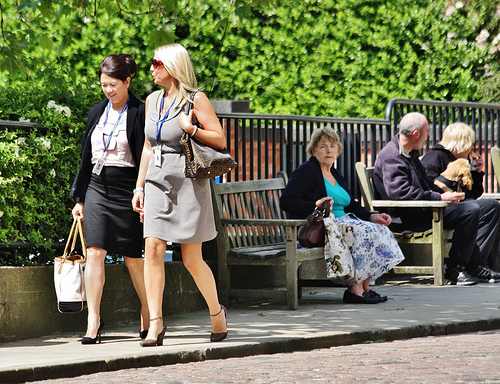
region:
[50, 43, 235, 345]
two women walking on the sidewalk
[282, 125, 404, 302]
a woman sitting on the bench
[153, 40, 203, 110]
the blonde hair of the woman on the sidewalk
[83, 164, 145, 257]
the woman's long black skirt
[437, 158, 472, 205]
the dog sitting on the bench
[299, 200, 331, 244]
the bag next to the old lady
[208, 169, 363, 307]
the bench the old lady is sitting on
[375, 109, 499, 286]
the old man sitting on the bench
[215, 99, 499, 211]
the black railing behind the benches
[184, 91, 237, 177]
the bag on the arm of the blonde woman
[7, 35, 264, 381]
two ladies walking on sidewalk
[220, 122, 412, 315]
woman sitting on bench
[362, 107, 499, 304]
people with dog sitting on bench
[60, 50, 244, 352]
women wearing badges around their necks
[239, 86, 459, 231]
black fence behind benches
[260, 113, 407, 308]
lady wearing blue-flowered skirt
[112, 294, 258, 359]
shoe with strap around ankle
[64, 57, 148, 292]
lady wearing black skirt and jacket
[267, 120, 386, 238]
woman wearing turquoise shirt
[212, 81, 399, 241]
brick wall behind benches and fence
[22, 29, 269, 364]
two women walking down sidewalk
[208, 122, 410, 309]
older woman sitting on bench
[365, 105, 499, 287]
two sitting on bench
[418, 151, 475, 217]
dog sitting on park bench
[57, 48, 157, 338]
woman wearing black skirt and coat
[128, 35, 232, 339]
woman wearing gray dress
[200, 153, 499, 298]
two wooden benches on sidewalk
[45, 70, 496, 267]
black fence behind benches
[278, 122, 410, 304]
woman wearing blue shirt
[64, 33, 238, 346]
two women wearing id badges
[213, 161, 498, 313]
wooden benches with faded green paint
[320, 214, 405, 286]
white and blue floral skirt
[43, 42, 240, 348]
2 women walking together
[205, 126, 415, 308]
woman in aqua top and floral skirt sitting on bench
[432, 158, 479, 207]
blond dog with black harness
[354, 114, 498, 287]
couple wearing dark clothing sitting with blond dog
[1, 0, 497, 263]
a grove of maple trees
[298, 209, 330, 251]
brown leather handbag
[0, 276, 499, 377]
paved cement sidewalk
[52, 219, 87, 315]
white, black and brown tote bag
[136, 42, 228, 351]
lady walking on the street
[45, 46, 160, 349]
lady walking on the street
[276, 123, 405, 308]
lady sitting on a bench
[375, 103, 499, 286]
person sitting on a bench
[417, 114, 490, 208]
person sitting on a bench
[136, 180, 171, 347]
leg of a lady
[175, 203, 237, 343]
leg of a lady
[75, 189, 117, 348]
leg of a lady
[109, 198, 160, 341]
leg of a lady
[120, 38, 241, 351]
lady with blonde hair